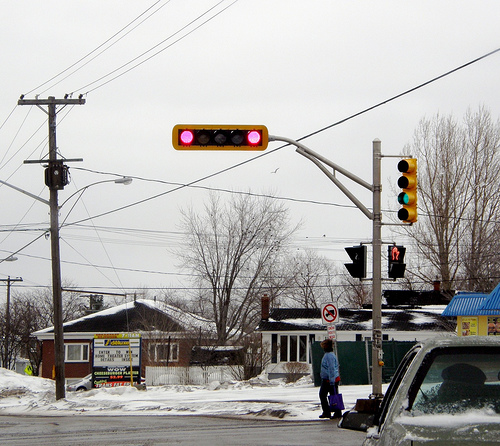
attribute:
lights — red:
[126, 99, 279, 155]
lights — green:
[380, 152, 451, 259]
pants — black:
[310, 376, 372, 426]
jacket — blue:
[307, 339, 368, 377]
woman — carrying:
[310, 330, 374, 438]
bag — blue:
[316, 370, 359, 420]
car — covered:
[381, 295, 490, 432]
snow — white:
[93, 360, 291, 412]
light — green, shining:
[380, 140, 440, 250]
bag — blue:
[325, 390, 347, 411]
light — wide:
[171, 118, 267, 154]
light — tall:
[394, 156, 423, 224]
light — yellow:
[394, 155, 420, 224]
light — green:
[396, 189, 412, 206]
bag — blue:
[326, 385, 347, 413]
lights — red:
[127, 106, 317, 196]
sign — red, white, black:
[307, 279, 356, 324]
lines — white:
[276, 333, 301, 353]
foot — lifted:
[304, 414, 350, 424]